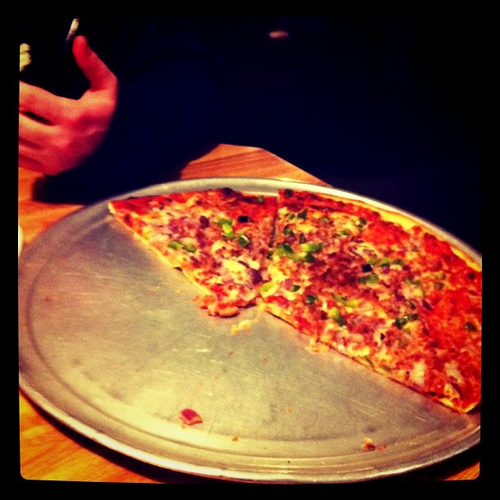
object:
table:
[18, 142, 480, 482]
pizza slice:
[101, 188, 275, 318]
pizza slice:
[261, 182, 417, 302]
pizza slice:
[266, 219, 480, 296]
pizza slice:
[264, 296, 483, 411]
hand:
[19, 34, 119, 175]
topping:
[180, 409, 202, 426]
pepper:
[167, 238, 196, 255]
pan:
[13, 177, 480, 481]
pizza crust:
[105, 186, 278, 209]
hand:
[17, 36, 115, 179]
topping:
[216, 219, 235, 239]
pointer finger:
[18, 83, 73, 121]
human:
[19, 10, 485, 253]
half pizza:
[103, 187, 480, 409]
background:
[22, 5, 499, 108]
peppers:
[280, 245, 312, 263]